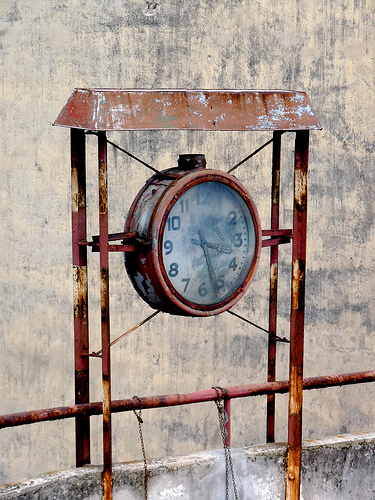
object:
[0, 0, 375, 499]
wall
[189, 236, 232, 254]
hands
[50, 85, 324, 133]
roof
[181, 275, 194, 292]
numbers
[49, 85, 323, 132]
top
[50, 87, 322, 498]
metal casing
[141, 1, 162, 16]
chip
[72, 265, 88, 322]
paint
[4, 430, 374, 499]
wall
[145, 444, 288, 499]
paint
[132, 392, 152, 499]
chain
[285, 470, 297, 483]
screw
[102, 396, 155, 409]
soot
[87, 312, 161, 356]
pole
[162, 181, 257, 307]
dirt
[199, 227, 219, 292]
hands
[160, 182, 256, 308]
face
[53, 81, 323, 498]
tin stand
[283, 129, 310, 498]
metal rod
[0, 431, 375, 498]
railing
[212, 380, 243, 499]
chain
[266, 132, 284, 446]
clock post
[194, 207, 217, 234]
glass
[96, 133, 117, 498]
pole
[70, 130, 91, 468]
pole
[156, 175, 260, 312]
clock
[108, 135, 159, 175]
rods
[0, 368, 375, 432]
rod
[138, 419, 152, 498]
wire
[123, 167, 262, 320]
cover